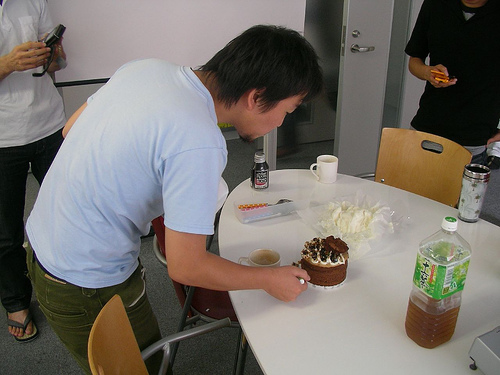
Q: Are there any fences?
A: No, there are no fences.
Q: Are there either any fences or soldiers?
A: No, there are no fences or soldiers.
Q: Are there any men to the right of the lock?
A: Yes, there is a man to the right of the lock.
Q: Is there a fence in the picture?
A: No, there are no fences.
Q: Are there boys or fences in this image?
A: No, there are no fences or boys.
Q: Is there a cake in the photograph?
A: Yes, there is a cake.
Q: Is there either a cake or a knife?
A: Yes, there is a cake.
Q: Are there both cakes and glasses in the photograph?
A: No, there is a cake but no glasses.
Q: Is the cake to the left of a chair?
A: No, the cake is to the right of a chair.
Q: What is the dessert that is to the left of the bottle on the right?
A: The dessert is a cake.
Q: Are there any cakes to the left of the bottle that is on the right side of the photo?
A: Yes, there is a cake to the left of the bottle.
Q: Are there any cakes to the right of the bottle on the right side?
A: No, the cake is to the left of the bottle.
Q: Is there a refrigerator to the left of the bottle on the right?
A: No, there is a cake to the left of the bottle.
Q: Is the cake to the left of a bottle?
A: Yes, the cake is to the left of a bottle.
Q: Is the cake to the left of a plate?
A: No, the cake is to the left of a bottle.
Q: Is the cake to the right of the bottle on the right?
A: No, the cake is to the left of the bottle.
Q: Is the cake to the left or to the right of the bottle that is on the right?
A: The cake is to the left of the bottle.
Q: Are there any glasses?
A: No, there are no glasses.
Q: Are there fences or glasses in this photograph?
A: No, there are no glasses or fences.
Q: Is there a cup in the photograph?
A: Yes, there is a cup.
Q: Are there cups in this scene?
A: Yes, there is a cup.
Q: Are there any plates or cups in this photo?
A: Yes, there is a cup.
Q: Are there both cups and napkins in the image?
A: No, there is a cup but no napkins.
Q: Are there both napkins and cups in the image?
A: No, there is a cup but no napkins.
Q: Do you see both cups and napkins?
A: No, there is a cup but no napkins.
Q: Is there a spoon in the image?
A: No, there are no spoons.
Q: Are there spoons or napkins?
A: No, there are no spoons or napkins.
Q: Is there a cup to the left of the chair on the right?
A: Yes, there is a cup to the left of the chair.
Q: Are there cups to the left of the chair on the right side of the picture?
A: Yes, there is a cup to the left of the chair.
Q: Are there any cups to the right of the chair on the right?
A: No, the cup is to the left of the chair.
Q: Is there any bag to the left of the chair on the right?
A: No, there is a cup to the left of the chair.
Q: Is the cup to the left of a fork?
A: No, the cup is to the left of a chair.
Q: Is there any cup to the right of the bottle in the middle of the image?
A: Yes, there is a cup to the right of the bottle.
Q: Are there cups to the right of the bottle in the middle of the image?
A: Yes, there is a cup to the right of the bottle.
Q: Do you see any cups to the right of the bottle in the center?
A: Yes, there is a cup to the right of the bottle.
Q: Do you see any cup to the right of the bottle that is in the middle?
A: Yes, there is a cup to the right of the bottle.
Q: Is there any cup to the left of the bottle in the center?
A: No, the cup is to the right of the bottle.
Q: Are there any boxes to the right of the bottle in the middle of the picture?
A: No, there is a cup to the right of the bottle.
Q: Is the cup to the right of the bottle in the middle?
A: Yes, the cup is to the right of the bottle.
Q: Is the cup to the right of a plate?
A: No, the cup is to the right of the bottle.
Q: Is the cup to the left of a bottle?
A: No, the cup is to the right of a bottle.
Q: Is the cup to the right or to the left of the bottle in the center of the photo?
A: The cup is to the right of the bottle.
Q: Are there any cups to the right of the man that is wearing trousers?
A: Yes, there is a cup to the right of the man.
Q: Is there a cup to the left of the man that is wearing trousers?
A: No, the cup is to the right of the man.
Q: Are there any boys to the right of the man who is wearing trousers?
A: No, there is a cup to the right of the man.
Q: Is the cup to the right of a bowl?
A: No, the cup is to the right of a man.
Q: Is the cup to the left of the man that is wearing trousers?
A: No, the cup is to the right of the man.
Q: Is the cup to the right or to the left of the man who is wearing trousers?
A: The cup is to the right of the man.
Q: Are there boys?
A: No, there are no boys.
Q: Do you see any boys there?
A: No, there are no boys.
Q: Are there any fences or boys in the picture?
A: No, there are no boys or fences.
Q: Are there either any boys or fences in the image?
A: No, there are no boys or fences.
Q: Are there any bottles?
A: Yes, there is a bottle.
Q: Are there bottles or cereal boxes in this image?
A: Yes, there is a bottle.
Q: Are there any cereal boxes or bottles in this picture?
A: Yes, there is a bottle.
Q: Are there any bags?
A: No, there are no bags.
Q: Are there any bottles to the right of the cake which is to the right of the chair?
A: Yes, there is a bottle to the right of the cake.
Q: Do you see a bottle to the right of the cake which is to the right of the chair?
A: Yes, there is a bottle to the right of the cake.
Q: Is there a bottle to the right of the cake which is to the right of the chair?
A: Yes, there is a bottle to the right of the cake.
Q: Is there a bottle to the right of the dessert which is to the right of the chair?
A: Yes, there is a bottle to the right of the cake.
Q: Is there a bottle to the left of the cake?
A: No, the bottle is to the right of the cake.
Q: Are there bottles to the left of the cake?
A: No, the bottle is to the right of the cake.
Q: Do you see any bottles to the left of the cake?
A: No, the bottle is to the right of the cake.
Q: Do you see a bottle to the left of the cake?
A: No, the bottle is to the right of the cake.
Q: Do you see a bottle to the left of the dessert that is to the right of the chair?
A: No, the bottle is to the right of the cake.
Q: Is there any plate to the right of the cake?
A: No, there is a bottle to the right of the cake.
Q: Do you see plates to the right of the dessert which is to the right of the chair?
A: No, there is a bottle to the right of the cake.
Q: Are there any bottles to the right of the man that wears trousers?
A: Yes, there is a bottle to the right of the man.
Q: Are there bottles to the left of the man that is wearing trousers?
A: No, the bottle is to the right of the man.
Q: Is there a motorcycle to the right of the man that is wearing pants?
A: No, there is a bottle to the right of the man.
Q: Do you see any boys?
A: No, there are no boys.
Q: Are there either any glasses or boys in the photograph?
A: No, there are no boys or glasses.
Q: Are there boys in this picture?
A: No, there are no boys.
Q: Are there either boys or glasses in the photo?
A: No, there are no boys or glasses.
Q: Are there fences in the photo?
A: No, there are no fences.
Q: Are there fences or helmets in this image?
A: No, there are no fences or helmets.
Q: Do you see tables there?
A: Yes, there is a table.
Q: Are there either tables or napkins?
A: Yes, there is a table.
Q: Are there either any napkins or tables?
A: Yes, there is a table.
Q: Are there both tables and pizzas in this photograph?
A: No, there is a table but no pizzas.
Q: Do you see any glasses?
A: No, there are no glasses.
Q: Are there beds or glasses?
A: No, there are no glasses or beds.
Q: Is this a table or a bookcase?
A: This is a table.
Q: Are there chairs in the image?
A: Yes, there is a chair.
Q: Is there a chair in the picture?
A: Yes, there is a chair.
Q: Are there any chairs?
A: Yes, there is a chair.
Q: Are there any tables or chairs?
A: Yes, there is a chair.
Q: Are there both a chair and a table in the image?
A: Yes, there are both a chair and a table.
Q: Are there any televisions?
A: No, there are no televisions.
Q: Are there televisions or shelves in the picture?
A: No, there are no televisions or shelves.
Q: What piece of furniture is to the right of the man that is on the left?
A: The piece of furniture is a chair.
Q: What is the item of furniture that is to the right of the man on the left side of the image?
A: The piece of furniture is a chair.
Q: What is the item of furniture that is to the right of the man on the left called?
A: The piece of furniture is a chair.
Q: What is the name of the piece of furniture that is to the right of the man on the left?
A: The piece of furniture is a chair.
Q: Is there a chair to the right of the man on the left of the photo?
A: Yes, there is a chair to the right of the man.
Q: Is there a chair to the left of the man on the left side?
A: No, the chair is to the right of the man.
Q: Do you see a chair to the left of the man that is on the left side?
A: No, the chair is to the right of the man.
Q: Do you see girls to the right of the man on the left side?
A: No, there is a chair to the right of the man.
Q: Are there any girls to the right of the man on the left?
A: No, there is a chair to the right of the man.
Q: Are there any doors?
A: Yes, there is a door.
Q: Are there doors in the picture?
A: Yes, there is a door.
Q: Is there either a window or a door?
A: Yes, there is a door.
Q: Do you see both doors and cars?
A: No, there is a door but no cars.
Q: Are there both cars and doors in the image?
A: No, there is a door but no cars.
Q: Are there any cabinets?
A: No, there are no cabinets.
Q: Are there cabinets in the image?
A: No, there are no cabinets.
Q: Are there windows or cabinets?
A: No, there are no cabinets or windows.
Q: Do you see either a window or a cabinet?
A: No, there are no cabinets or windows.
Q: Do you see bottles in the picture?
A: Yes, there is a bottle.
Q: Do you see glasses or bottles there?
A: Yes, there is a bottle.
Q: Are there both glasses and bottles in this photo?
A: No, there is a bottle but no glasses.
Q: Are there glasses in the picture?
A: No, there are no glasses.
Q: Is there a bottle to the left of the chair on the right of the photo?
A: Yes, there is a bottle to the left of the chair.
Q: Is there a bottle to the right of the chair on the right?
A: No, the bottle is to the left of the chair.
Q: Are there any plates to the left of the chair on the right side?
A: No, there is a bottle to the left of the chair.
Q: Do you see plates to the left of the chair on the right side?
A: No, there is a bottle to the left of the chair.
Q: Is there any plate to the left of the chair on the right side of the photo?
A: No, there is a bottle to the left of the chair.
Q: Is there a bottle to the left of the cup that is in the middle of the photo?
A: Yes, there is a bottle to the left of the cup.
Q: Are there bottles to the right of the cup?
A: No, the bottle is to the left of the cup.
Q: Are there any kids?
A: No, there are no kids.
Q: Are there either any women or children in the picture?
A: No, there are no children or women.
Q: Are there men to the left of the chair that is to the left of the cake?
A: Yes, there is a man to the left of the chair.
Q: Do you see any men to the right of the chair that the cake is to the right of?
A: No, the man is to the left of the chair.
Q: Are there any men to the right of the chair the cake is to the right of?
A: No, the man is to the left of the chair.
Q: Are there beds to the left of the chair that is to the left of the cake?
A: No, there is a man to the left of the chair.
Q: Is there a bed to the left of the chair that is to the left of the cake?
A: No, there is a man to the left of the chair.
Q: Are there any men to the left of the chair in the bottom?
A: Yes, there is a man to the left of the chair.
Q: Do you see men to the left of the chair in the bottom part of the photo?
A: Yes, there is a man to the left of the chair.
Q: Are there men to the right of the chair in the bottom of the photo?
A: No, the man is to the left of the chair.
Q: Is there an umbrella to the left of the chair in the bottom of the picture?
A: No, there is a man to the left of the chair.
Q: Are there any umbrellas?
A: No, there are no umbrellas.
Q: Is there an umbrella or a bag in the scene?
A: No, there are no umbrellas or bags.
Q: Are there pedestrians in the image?
A: No, there are no pedestrians.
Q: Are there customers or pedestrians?
A: No, there are no pedestrians or customers.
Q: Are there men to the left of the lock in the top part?
A: Yes, there is a man to the left of the lock.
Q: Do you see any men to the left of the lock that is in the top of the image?
A: Yes, there is a man to the left of the lock.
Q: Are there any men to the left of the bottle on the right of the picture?
A: Yes, there is a man to the left of the bottle.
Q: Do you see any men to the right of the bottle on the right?
A: No, the man is to the left of the bottle.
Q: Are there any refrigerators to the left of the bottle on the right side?
A: No, there is a man to the left of the bottle.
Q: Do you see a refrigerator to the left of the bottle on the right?
A: No, there is a man to the left of the bottle.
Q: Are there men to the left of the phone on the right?
A: Yes, there is a man to the left of the telephone.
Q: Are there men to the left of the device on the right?
A: Yes, there is a man to the left of the telephone.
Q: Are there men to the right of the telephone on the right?
A: No, the man is to the left of the phone.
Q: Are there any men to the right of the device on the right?
A: No, the man is to the left of the phone.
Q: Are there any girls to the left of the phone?
A: No, there is a man to the left of the phone.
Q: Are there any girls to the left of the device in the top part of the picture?
A: No, there is a man to the left of the phone.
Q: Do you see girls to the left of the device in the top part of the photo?
A: No, there is a man to the left of the phone.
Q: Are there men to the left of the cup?
A: Yes, there is a man to the left of the cup.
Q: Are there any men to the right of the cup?
A: No, the man is to the left of the cup.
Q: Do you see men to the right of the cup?
A: No, the man is to the left of the cup.